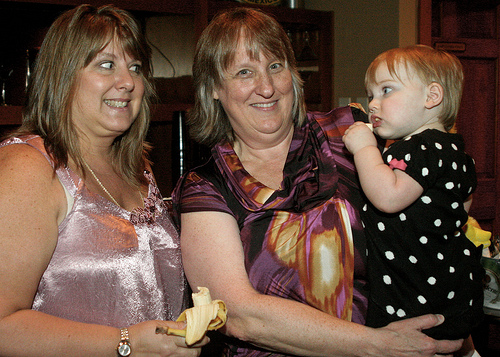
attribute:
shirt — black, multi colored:
[169, 102, 387, 355]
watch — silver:
[115, 326, 132, 354]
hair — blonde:
[365, 43, 466, 132]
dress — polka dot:
[373, 128, 484, 316]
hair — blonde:
[29, 7, 466, 157]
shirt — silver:
[4, 121, 194, 353]